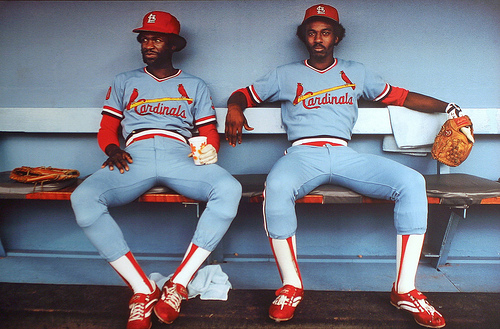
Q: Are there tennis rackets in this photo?
A: No, there are no tennis rackets.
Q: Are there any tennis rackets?
A: No, there are no tennis rackets.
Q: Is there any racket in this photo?
A: No, there are no rackets.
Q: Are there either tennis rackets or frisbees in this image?
A: No, there are no tennis rackets or frisbees.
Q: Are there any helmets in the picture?
A: No, there are no helmets.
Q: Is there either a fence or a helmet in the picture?
A: No, there are no helmets or fences.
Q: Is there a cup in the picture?
A: Yes, there is a cup.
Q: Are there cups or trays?
A: Yes, there is a cup.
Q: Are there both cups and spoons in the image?
A: No, there is a cup but no spoons.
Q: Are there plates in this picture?
A: No, there are no plates.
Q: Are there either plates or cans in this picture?
A: No, there are no plates or cans.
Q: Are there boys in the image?
A: No, there are no boys.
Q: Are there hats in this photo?
A: Yes, there is a hat.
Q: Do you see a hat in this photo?
A: Yes, there is a hat.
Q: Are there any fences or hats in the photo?
A: Yes, there is a hat.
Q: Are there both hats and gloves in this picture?
A: Yes, there are both a hat and gloves.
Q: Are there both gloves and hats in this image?
A: Yes, there are both a hat and gloves.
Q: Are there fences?
A: No, there are no fences.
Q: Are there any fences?
A: No, there are no fences.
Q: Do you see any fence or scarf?
A: No, there are no fences or scarves.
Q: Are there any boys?
A: No, there are no boys.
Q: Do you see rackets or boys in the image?
A: No, there are no boys or rackets.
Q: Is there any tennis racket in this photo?
A: No, there are no rackets.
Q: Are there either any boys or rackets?
A: No, there are no rackets or boys.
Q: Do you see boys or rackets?
A: No, there are no rackets or boys.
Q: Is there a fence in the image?
A: No, there are no fences.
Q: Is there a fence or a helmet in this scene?
A: No, there are no fences or helmets.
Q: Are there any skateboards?
A: No, there are no skateboards.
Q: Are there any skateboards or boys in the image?
A: No, there are no skateboards or boys.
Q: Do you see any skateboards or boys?
A: No, there are no skateboards or boys.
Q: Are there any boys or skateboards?
A: No, there are no skateboards or boys.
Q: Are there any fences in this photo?
A: No, there are no fences.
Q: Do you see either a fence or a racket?
A: No, there are no fences or rackets.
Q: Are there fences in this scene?
A: No, there are no fences.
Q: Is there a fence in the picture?
A: No, there are no fences.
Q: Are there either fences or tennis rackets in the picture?
A: No, there are no fences or tennis rackets.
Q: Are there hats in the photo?
A: Yes, there is a hat.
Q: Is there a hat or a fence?
A: Yes, there is a hat.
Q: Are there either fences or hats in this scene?
A: Yes, there is a hat.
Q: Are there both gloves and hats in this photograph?
A: Yes, there are both a hat and gloves.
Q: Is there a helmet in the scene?
A: No, there are no helmets.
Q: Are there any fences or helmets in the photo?
A: No, there are no helmets or fences.